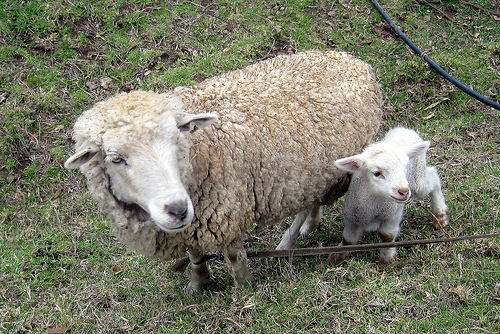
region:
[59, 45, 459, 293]
a sheep beside a lamb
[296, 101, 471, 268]
a lamb beside its mother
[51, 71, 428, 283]
a sheep beside its lamb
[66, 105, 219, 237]
the head of a sheep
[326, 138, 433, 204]
the head of a lamb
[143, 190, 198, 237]
the nose of a sheep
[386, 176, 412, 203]
the nose of a lamb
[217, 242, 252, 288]
the leg of a sheep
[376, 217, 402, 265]
the leg of a lamb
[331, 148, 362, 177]
the ear of a lamb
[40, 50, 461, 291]
a sheep on grassy field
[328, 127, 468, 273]
an infant sheep on grassy field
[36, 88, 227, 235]
head of a sheep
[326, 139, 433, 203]
head of an infant sheep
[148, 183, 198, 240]
mouth of a sheep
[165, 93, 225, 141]
ears of a sheep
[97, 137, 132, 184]
eyes of a sheep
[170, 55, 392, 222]
body of a sheep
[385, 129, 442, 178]
body of a sheep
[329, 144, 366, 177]
ears of an infant sheep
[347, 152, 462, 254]
the sheep is white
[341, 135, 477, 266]
the sheep is looking to the right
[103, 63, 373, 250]
the sheep is brown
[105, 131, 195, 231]
the face is white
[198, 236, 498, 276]
rope is tied to the sheep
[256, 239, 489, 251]
the rope is brown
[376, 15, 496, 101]
the cable is black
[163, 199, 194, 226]
the nose is black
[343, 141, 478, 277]
the lamb is small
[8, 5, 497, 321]
the photo was taken during the day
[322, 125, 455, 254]
a small white baby lamb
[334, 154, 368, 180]
a pointed white ear with pink inside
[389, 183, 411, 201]
an adorable pink and black nose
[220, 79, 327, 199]
a brown white coat of wool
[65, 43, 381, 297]
a woolly brown and white mama sheep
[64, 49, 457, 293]
a mama sheep with her baby lamb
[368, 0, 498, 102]
a black hose lying on the ground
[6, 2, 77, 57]
small dark green weeds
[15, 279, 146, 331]
a patch of dead brown grass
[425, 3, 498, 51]
brown leaves on short green grass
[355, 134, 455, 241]
A small beautiful sheep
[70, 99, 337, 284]
A brown dirty sheep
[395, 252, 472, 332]
A green and brown grass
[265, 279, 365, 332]
A green and brown grass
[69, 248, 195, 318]
A green and brown grass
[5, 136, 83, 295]
A green and brown grass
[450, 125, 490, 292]
A green and brown grass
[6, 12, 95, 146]
A green and brown grass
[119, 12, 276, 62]
A green and brown grass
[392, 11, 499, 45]
A green and brown grass